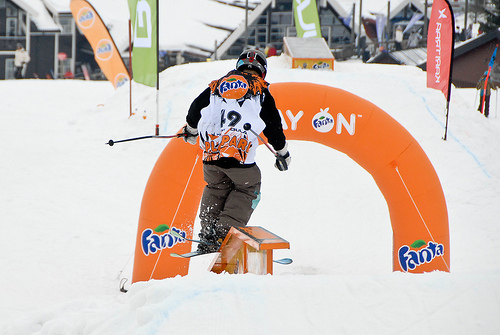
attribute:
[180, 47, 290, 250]
person — jumping, walking, competing, skiing, performing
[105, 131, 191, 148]
ski pole — bent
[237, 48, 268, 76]
helmet — gray, black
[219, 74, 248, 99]
advertisement — fanta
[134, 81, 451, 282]
inflatable — advertisement, orange, ring, branded, tube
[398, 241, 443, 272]
logo — fanta, blue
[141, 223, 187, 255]
logo — fanta, blue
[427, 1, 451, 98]
banner — red, white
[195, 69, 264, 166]
vest — white, curled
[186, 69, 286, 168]
jacket — white, black, orange, blue, ski jacket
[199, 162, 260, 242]
pants — brown, snow pants, gray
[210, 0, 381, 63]
building — a frame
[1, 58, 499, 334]
snow — deep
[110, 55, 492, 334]
slope — slanted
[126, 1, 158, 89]
sign — green, white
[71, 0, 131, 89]
banner — slanted, advertisement, orange, blue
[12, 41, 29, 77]
person — standing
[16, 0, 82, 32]
roof — slanting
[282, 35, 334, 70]
jump — small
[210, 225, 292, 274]
slide — small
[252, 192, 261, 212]
patch — blue